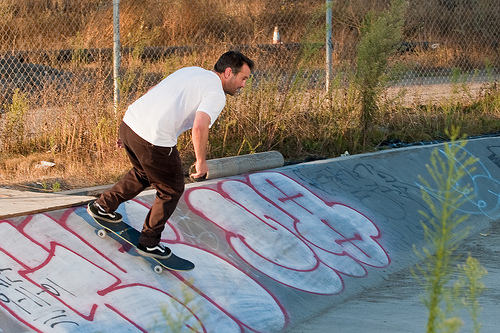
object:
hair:
[214, 51, 255, 74]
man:
[87, 51, 254, 259]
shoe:
[136, 243, 173, 258]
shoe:
[87, 202, 124, 223]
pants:
[87, 121, 184, 258]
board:
[87, 202, 195, 275]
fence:
[1, 1, 497, 124]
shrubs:
[291, 53, 407, 137]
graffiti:
[202, 180, 396, 286]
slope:
[0, 158, 500, 332]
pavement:
[0, 180, 499, 332]